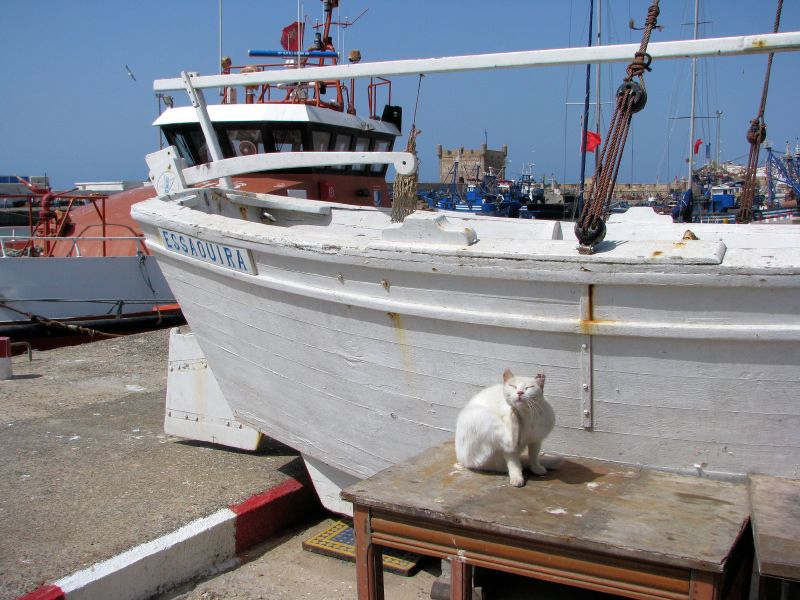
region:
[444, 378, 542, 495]
cat on the table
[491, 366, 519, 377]
ear of the cat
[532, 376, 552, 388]
ear of the cat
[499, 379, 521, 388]
eye of the cat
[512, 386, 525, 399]
nose of the cat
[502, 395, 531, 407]
mouth of the cat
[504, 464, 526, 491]
paw of the cat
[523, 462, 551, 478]
paw of the cat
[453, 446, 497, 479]
leg of the cat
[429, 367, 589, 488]
a cat that is white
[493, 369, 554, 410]
the head of a cat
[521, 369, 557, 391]
the left ear of a cat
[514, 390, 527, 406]
the nose of a cat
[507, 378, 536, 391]
the eyes of a cat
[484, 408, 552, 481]
the front legs of a cat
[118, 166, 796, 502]
a boat that is white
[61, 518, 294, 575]
the ledge of a sidewalk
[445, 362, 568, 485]
a white colored cat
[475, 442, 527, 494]
the left paw of a cat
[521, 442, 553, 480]
the right paw of a cat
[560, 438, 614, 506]
the shadow of a cat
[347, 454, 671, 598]
a small brown table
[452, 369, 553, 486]
seated cat scratching neck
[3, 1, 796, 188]
clear blue daytime sky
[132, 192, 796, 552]
body of white boat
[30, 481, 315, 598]
red and white curb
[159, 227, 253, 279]
sign with blue letters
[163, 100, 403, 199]
wheel house of boat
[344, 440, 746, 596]
table with dirty top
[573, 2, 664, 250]
multiple ropes on pulley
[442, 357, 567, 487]
white cat on table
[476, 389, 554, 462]
beauty cat on the table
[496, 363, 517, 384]
small pink ear of te cat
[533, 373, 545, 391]
small letf ear of the cat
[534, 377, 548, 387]
small pink era of the cat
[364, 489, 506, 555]
wooden brown table on the pavement